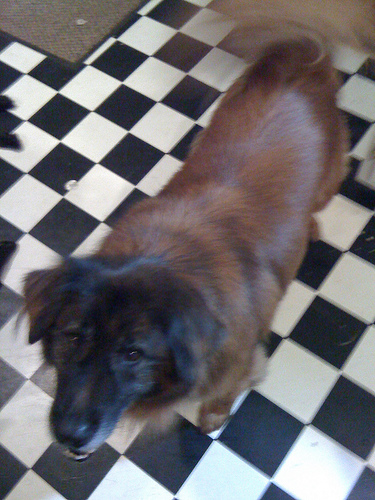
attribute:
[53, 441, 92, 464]
teeth — white 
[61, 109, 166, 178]
pattern — checkered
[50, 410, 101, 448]
nose — black 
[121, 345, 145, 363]
brown eye — Brown 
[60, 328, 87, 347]
brown eye — Brown 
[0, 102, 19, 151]
paws — black 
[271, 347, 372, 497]
floor — white , black 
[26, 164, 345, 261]
dog's body — brown 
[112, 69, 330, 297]
back — brown 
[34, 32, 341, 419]
dog — brown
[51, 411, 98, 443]
nose — black 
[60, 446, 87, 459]
teeth — white 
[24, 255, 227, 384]
ears — black 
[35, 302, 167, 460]
face — black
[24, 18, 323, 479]
dog — brown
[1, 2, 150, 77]
rug — brown 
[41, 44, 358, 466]
hair — Brown 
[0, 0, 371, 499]
floor — tiled, tile, black , white 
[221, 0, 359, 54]
tail — brown